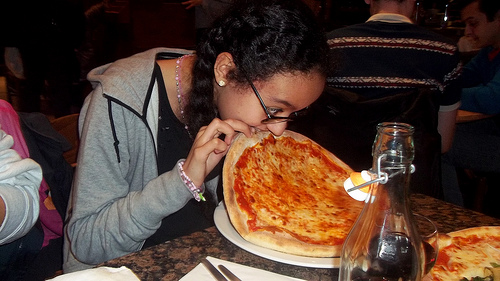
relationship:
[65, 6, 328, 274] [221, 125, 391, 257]
girl eating pizza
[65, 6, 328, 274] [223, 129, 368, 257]
girl eating pizza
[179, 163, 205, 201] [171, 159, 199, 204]
bracelet worn on wrist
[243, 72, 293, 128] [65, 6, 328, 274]
glasses worn by girl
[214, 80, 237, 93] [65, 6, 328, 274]
earring worn by girl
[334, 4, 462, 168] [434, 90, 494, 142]
man sitting at table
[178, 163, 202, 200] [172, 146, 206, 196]
bracelet on a wrist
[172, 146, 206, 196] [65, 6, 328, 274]
wrist on a girl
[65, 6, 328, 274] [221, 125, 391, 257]
girl eating a pizza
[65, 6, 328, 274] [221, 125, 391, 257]
girl biting into a pizza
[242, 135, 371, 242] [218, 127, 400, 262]
cheese on a pizza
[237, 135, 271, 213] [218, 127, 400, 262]
tomato on a pizza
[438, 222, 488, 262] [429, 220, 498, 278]
tomato on a pizza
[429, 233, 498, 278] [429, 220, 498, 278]
cheese on a pizza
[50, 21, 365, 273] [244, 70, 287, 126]
girl wearing glasses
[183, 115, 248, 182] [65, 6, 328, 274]
hand on a girl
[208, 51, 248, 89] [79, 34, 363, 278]
ear on a girl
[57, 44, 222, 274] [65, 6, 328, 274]
sweater on a girl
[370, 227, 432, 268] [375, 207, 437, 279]
wine in a glass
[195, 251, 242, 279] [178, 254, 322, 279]
silverware on a napkin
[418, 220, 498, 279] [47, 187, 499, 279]
pizza on a table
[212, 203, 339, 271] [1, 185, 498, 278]
plate on a table